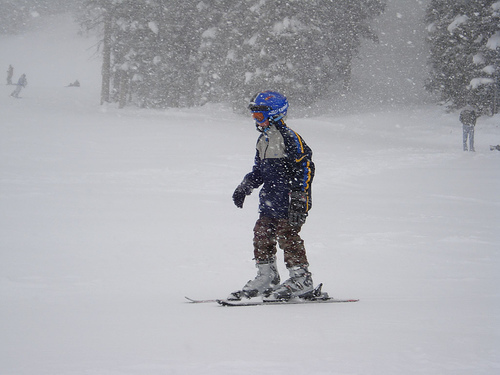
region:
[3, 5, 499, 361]
snow is falling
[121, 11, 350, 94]
snowflakes falling to the ground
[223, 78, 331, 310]
skier wearing a blue helmet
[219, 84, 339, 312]
person wears a winter coat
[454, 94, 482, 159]
person stands on side of field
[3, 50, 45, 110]
skiers coming down the hill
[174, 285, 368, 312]
skis are short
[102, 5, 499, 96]
snow over the trees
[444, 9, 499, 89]
snowflakes on branches of tree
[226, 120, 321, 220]
coat has yellow stripe on sleeve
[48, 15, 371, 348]
person skiing in heavy snowfall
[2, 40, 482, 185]
other skiers and man in background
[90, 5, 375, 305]
dense trees behind skier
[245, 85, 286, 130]
skier wearing blue helmet and goggles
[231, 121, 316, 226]
arms loosely at sides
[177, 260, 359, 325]
one foot in front of the other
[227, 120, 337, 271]
white dots of snow against jacket and pants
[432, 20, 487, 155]
man looking back toward trees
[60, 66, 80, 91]
skier laying in snow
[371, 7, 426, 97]
large flakes against gray background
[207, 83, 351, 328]
This is a person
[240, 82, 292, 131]
Head of a person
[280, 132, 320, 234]
Hand of a person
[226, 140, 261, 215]
Hand of a person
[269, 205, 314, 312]
Leg of a person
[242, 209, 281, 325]
Leg of a person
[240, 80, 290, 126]
This is a Protective helmet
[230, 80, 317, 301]
This is a Protective gear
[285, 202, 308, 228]
This is a Protective gloves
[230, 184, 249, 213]
This is a Protective gloves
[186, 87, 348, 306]
a kid in the snow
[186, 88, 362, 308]
a kid in a snow suite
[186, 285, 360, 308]
a set of skis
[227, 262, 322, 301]
a set of grey ski boots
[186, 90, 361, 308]
a kid skiing in the snow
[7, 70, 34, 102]
someone skiing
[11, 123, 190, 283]
a patch of white snow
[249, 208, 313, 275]
a pair of brown pants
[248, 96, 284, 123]
a pair of snow googles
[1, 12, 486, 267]
snow falling on a kid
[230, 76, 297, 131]
The kid has on a helmet.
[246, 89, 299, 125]
The kid's helmet is blue.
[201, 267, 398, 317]
The kid has on skis.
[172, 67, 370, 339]
This kid is skiing.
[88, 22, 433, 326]
It is snowing very hard.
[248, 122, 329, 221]
The kids jacket is blue, yellow, and gray.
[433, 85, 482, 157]
This person is standing in the background.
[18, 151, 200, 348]
the ground is covered in snow.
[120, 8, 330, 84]
The trees in the background are covered in snow.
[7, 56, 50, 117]
These people are skiing.